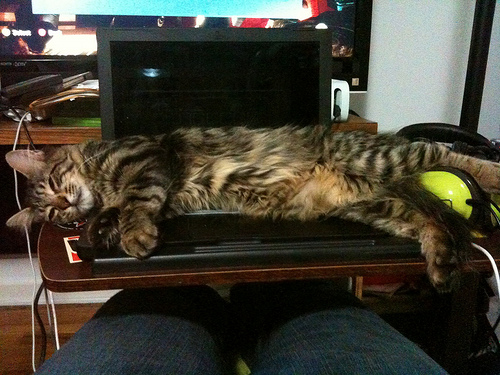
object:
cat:
[23, 122, 463, 248]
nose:
[62, 193, 78, 213]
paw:
[116, 198, 157, 255]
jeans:
[70, 301, 411, 374]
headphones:
[421, 167, 491, 222]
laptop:
[89, 25, 350, 128]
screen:
[315, 34, 343, 121]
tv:
[21, 26, 56, 49]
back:
[421, 17, 446, 43]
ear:
[11, 132, 55, 187]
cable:
[472, 244, 500, 356]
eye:
[38, 167, 66, 192]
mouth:
[70, 184, 93, 217]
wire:
[27, 251, 44, 288]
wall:
[412, 63, 438, 111]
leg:
[342, 136, 497, 180]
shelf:
[42, 125, 86, 149]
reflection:
[139, 55, 167, 97]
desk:
[1, 59, 72, 129]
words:
[15, 26, 31, 42]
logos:
[38, 21, 48, 42]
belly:
[187, 159, 357, 210]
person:
[252, 345, 372, 366]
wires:
[5, 134, 31, 212]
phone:
[28, 96, 104, 121]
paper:
[67, 237, 87, 265]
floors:
[60, 307, 82, 329]